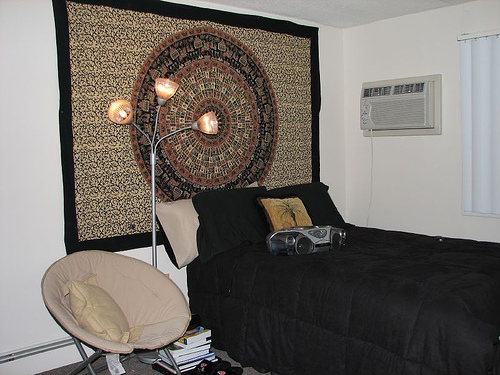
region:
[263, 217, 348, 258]
this is a radio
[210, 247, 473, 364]
this is a bed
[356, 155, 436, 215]
this is the wall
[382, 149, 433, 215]
the wall is white in color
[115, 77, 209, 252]
this is a lightstand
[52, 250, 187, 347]
this is a chair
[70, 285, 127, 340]
this is a pillow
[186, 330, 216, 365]
this is a heap of books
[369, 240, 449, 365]
the bedding is black in color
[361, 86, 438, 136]
this is an air conditioner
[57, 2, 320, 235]
a large rug on the wall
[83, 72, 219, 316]
a tall lamp with flexible lights next to the bed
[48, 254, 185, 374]
a round chair next to the bed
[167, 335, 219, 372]
a pile of magazine next to the bed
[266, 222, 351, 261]
a stereo on the box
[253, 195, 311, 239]
a small square pillow on the bed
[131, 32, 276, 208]
a circular design in the center of the rug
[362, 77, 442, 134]
an air conditioner on the wall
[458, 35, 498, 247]
vertical blind in the room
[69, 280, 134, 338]
the pillow in the chair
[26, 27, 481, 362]
a comfy personal bedroom.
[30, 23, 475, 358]
a nice small bedroom area.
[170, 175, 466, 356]
a bed with a radio on it.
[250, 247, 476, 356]
Some dark bedsheets on a bed.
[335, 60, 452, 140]
An air conditioning unit.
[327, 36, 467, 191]
An air conditioner unit on the wall.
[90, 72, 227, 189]
A lamp with three bulbs.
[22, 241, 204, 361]
A beige sitting chair.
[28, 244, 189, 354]
A sitting chair with pillow.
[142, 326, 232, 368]
An assortment of books on floor.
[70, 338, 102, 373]
Crossed silver metal X chair legs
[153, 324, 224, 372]
Pile of books to the right of the chair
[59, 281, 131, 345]
Pillow on the chair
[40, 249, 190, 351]
Cushioned part of the round chair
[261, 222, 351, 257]
Boombox on the bed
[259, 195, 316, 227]
Square tan and black pillow behind the boombox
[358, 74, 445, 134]
Air conditioner on the wall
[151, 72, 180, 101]
Highest of the three lights on the lamp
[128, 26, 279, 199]
Round design in the center of the wall hanging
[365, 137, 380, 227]
Cord from the air conditioner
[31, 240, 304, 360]
Tan chair with silver base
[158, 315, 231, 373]
Stack of books on the floor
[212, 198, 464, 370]
Black blanket on a bed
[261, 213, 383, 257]
Stereo on a bed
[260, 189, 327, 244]
Palm tree pillow on a bed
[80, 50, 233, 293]
Silver lamp next to a bed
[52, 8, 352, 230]
Wall decor hanging on a wall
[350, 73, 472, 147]
Air conditioner on a wall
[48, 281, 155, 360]
Tan pillow on a chair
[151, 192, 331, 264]
Several pillows on a bed